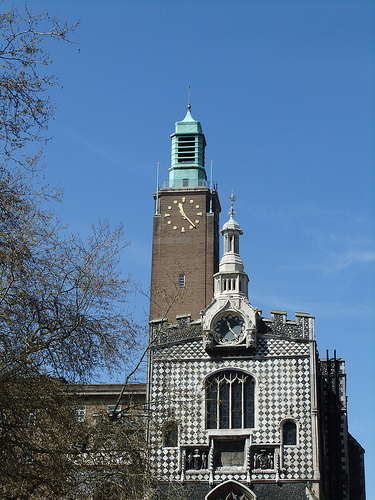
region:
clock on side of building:
[162, 195, 203, 236]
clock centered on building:
[207, 303, 248, 348]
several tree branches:
[0, 246, 124, 483]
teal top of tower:
[161, 110, 212, 187]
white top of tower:
[210, 187, 251, 301]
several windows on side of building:
[199, 366, 261, 437]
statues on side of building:
[180, 445, 210, 466]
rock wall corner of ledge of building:
[260, 298, 314, 335]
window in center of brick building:
[176, 267, 188, 289]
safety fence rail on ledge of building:
[159, 176, 204, 187]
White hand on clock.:
[228, 328, 238, 342]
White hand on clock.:
[224, 320, 234, 329]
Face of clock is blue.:
[220, 323, 255, 349]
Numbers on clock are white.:
[219, 314, 252, 360]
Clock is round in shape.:
[220, 307, 260, 365]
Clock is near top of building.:
[205, 305, 257, 357]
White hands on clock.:
[167, 200, 215, 252]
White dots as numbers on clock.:
[165, 195, 213, 242]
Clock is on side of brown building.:
[160, 194, 204, 241]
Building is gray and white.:
[274, 373, 301, 403]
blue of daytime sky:
[0, 2, 372, 477]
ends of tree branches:
[21, 8, 98, 236]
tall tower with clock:
[150, 82, 220, 316]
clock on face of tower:
[164, 196, 201, 232]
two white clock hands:
[177, 203, 195, 228]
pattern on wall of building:
[153, 360, 312, 478]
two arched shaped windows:
[162, 416, 300, 449]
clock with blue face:
[217, 316, 243, 340]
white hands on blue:
[224, 319, 239, 339]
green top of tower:
[176, 106, 206, 124]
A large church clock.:
[163, 191, 204, 232]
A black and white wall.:
[145, 333, 313, 485]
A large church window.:
[204, 367, 256, 432]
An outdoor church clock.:
[210, 308, 247, 346]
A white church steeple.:
[212, 190, 249, 296]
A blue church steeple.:
[165, 84, 215, 189]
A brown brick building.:
[151, 188, 220, 321]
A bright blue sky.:
[0, 0, 373, 498]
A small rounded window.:
[162, 420, 179, 450]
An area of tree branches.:
[0, 0, 228, 498]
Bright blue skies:
[151, 23, 294, 91]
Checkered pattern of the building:
[265, 366, 301, 410]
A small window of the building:
[281, 420, 297, 446]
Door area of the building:
[215, 438, 241, 465]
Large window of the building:
[211, 377, 247, 425]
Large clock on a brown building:
[163, 196, 205, 232]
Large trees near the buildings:
[1, 219, 130, 386]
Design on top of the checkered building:
[221, 189, 250, 309]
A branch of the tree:
[114, 365, 128, 416]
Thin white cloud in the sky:
[315, 226, 367, 265]